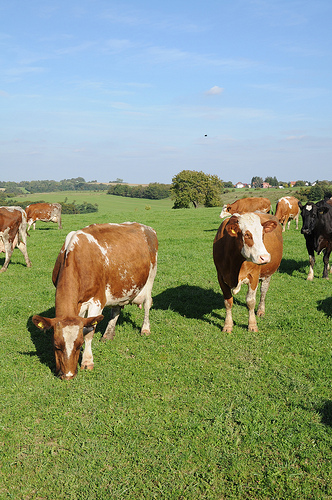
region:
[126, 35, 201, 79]
clouds in the sky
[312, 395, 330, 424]
shadow on the ground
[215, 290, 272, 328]
legs of the cow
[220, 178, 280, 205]
buildings in the distance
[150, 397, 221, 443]
grass on the ground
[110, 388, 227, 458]
light hitting the ground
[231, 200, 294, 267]
head of the cow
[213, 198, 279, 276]
white and brown cow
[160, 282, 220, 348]
shadow of the cow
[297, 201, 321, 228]
black and white cow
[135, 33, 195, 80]
clouds above the ground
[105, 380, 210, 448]
green grass on ground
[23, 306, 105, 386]
head of the animal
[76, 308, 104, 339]
ear of the animal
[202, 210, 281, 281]
brown and white cow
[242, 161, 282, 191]
buildings in the background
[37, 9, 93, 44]
blue sky behind clouds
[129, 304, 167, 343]
leg of the cow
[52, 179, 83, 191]
trees in the distance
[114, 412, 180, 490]
the grass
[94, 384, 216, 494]
the grass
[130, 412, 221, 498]
the grass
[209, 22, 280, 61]
The sky is blue.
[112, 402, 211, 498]
The grass is green.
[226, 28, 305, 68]
The sky is clear.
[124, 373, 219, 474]
The grass is short.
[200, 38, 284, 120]
A few clouds are in the sky.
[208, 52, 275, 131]
The clouds are white.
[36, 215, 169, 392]
The cow is brown and white.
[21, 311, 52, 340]
The cow has a tag in its ear.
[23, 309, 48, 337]
The tag is yellow.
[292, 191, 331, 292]
The cow is black and white.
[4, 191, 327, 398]
herd of cattle in field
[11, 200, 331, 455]
cattle are grazing in field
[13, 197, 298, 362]
most cattle are brown and white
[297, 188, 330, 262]
cow is dark brown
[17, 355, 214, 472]
grass is green and short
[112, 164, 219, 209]
numerous trees in background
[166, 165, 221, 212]
trees are tall and green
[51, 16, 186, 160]
sky is blue and has few clouds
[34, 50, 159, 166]
clouds are thin and white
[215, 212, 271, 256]
cow has white face